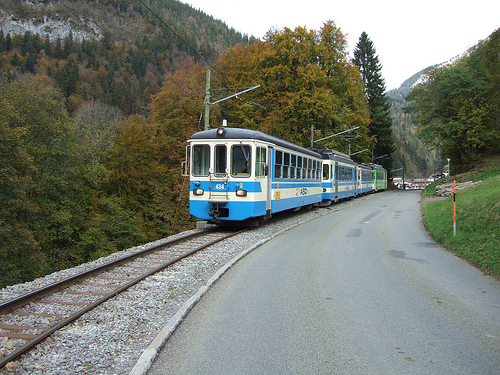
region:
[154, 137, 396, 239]
blue and white train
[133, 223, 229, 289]
track under the train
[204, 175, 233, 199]
white number on front of train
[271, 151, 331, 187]
windows on side of train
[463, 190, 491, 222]
grass next to the street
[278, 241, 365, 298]
gray street next to train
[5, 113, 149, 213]
trees next to the train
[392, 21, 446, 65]
sky above the grass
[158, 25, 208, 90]
wire above the train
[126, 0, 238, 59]
trees on the hill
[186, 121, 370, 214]
A train on the track.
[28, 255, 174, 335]
The tracks have gravel between them.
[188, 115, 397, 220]
The train is enroute to destination.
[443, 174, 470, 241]
An orange pole sticking out of grass.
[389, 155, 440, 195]
Small town in the background.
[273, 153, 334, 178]
The train has windows.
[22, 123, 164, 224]
The side of the tracks is surrounded by trees.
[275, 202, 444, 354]
A road into town.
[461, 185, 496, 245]
The grass on hill is green.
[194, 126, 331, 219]
The train is blue and white.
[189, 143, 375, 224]
train is blue and white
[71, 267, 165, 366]
gravel near the tracks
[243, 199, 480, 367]
road near the train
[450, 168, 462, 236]
orange and black pole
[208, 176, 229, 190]
number on the train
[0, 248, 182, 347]
two tracks for the train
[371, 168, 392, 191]
green car in the back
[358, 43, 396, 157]
tall tree in background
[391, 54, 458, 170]
mountains in the landscape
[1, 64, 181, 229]
many shrubs along the side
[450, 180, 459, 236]
The pole is orange.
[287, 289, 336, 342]
The ground is concrete.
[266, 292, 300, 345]
The ground is grey.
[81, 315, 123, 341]
The road is made of gravel.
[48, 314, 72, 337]
The tracks are made of steel.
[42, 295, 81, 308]
The tracks are made of wood.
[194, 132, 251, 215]
The front of the train is blue and white.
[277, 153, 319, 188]
The side of the train has windows.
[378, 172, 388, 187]
The last train is green.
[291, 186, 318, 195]
The side of the train has blue writing.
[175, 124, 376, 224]
three blue and white train cars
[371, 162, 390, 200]
green car of train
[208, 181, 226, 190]
white numbers on blue background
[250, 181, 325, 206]
white stripes down side of first train car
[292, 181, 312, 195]
blue lettering on white background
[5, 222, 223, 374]
tracks in front of train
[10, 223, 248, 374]
gravel surrounding train tracks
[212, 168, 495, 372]
path running beside train tracks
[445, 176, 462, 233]
orange, black, and white marker in grass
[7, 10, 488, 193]
tree covered mountains around train tracks